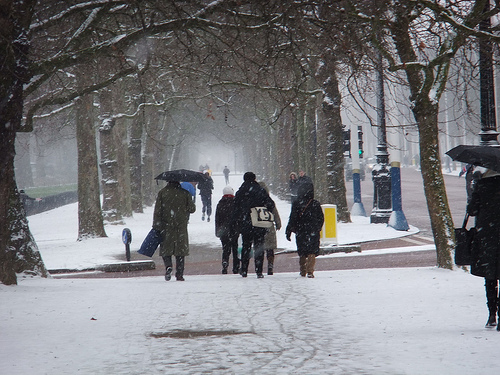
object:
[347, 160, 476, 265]
street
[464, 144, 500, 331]
person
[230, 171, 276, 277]
person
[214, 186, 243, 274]
person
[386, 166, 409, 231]
blue post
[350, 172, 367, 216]
blue post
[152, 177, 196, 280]
man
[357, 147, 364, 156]
signal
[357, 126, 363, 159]
light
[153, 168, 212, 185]
umbrella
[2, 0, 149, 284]
tree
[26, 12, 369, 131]
branches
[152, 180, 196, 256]
coat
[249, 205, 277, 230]
bag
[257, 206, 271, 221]
face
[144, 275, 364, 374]
tracks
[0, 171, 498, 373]
snow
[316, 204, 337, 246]
box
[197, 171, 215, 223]
person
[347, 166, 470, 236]
asphalt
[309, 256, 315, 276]
boots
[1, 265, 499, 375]
sidewalk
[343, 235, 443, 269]
concrete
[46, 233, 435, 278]
sidewalk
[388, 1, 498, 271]
tree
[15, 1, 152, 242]
tree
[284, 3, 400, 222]
tree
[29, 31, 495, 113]
snow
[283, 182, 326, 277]
person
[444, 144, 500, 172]
umbrella